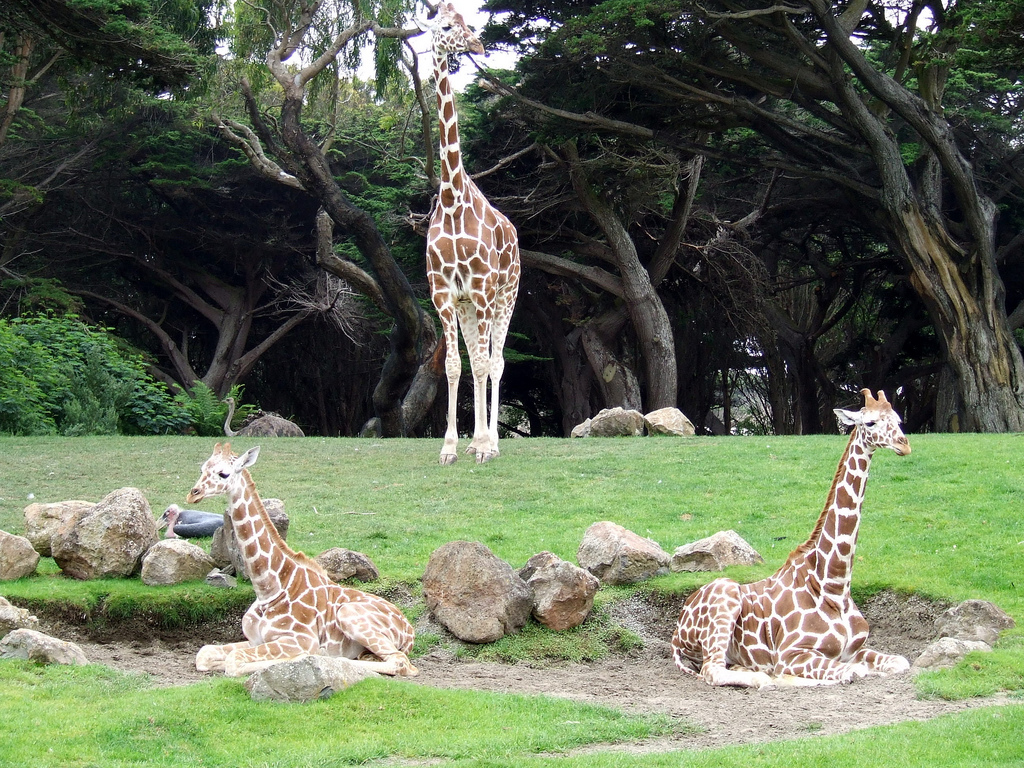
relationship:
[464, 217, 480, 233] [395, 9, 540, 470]
spot on giraffe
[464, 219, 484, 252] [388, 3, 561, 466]
spot on giraffe